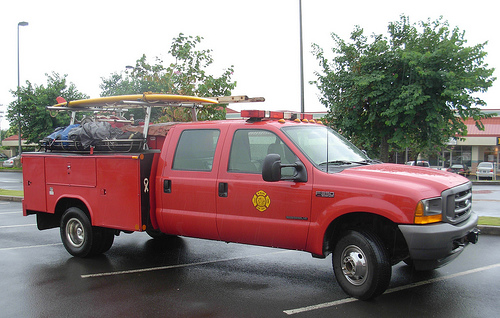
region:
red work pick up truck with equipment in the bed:
[18, 91, 481, 301]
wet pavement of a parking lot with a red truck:
[0, 192, 494, 315]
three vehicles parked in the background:
[369, 159, 496, 185]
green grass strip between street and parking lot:
[0, 179, 498, 236]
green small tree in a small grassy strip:
[306, 11, 494, 161]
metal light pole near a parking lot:
[11, 18, 30, 167]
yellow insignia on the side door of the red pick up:
[249, 187, 271, 215]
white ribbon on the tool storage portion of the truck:
[141, 174, 153, 194]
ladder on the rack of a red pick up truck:
[59, 91, 267, 107]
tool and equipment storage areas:
[18, 146, 153, 235]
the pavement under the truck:
[3, 206, 455, 315]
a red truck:
[17, 98, 477, 280]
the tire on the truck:
[334, 234, 394, 307]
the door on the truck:
[219, 125, 314, 242]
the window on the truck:
[226, 131, 288, 175]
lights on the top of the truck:
[241, 105, 313, 120]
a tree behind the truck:
[325, 18, 459, 145]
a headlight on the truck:
[416, 201, 446, 214]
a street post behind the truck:
[8, 20, 40, 152]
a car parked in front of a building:
[473, 163, 494, 180]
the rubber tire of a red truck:
[56, 211, 104, 251]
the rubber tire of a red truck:
[329, 227, 387, 295]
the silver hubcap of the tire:
[64, 218, 86, 250]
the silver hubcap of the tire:
[340, 243, 370, 285]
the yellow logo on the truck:
[250, 191, 269, 215]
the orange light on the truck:
[410, 215, 442, 225]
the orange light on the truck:
[415, 200, 422, 213]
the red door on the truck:
[162, 124, 223, 233]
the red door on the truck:
[218, 124, 314, 249]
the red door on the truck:
[43, 157, 102, 191]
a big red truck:
[6, 87, 485, 299]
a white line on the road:
[283, 277, 495, 317]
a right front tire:
[309, 212, 390, 314]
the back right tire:
[38, 203, 123, 260]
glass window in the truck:
[156, 115, 388, 186]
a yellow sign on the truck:
[244, 186, 295, 218]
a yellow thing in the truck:
[3, 80, 251, 132]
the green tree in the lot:
[290, 2, 499, 167]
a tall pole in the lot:
[290, 2, 309, 126]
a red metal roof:
[425, 100, 499, 157]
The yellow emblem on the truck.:
[247, 185, 274, 222]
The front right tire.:
[330, 230, 383, 295]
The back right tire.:
[54, 203, 101, 262]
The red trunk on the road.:
[22, 78, 497, 295]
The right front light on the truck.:
[406, 195, 446, 232]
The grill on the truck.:
[444, 188, 479, 222]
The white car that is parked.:
[471, 160, 498, 185]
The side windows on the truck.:
[177, 128, 294, 193]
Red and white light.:
[240, 105, 315, 122]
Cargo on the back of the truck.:
[45, 123, 150, 158]